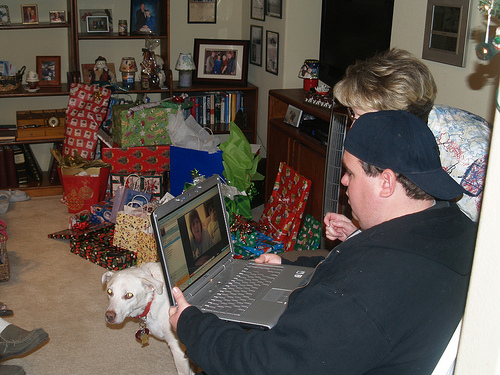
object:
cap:
[167, 108, 489, 344]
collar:
[117, 262, 164, 325]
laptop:
[144, 173, 324, 335]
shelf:
[0, 0, 270, 201]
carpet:
[27, 260, 86, 319]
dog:
[94, 250, 199, 375]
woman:
[322, 40, 500, 230]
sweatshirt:
[165, 195, 485, 375]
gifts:
[37, 78, 331, 268]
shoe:
[0, 316, 58, 366]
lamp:
[168, 48, 201, 92]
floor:
[0, 98, 199, 375]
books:
[164, 88, 259, 141]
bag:
[159, 134, 236, 209]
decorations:
[84, 54, 117, 94]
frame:
[180, 34, 257, 94]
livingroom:
[0, 0, 500, 375]